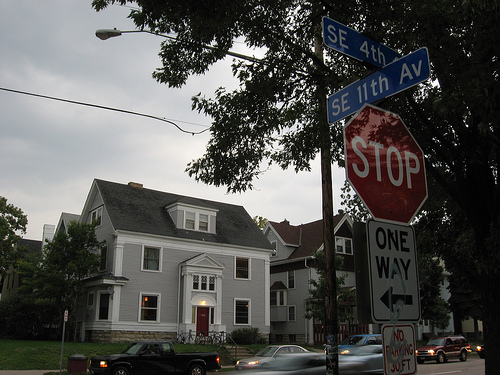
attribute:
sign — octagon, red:
[339, 100, 435, 230]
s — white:
[350, 135, 370, 181]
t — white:
[367, 136, 388, 186]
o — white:
[385, 139, 406, 189]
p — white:
[402, 149, 423, 193]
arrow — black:
[380, 285, 418, 314]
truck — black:
[87, 338, 226, 374]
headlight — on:
[88, 358, 95, 368]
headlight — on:
[99, 359, 109, 370]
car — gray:
[234, 340, 326, 372]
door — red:
[194, 308, 212, 339]